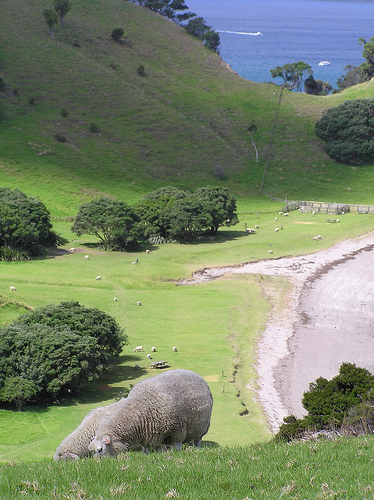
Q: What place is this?
A: It is a field.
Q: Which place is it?
A: It is a field.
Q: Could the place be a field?
A: Yes, it is a field.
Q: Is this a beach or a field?
A: It is a field.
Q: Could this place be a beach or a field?
A: It is a field.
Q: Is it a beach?
A: No, it is a field.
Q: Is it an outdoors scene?
A: Yes, it is outdoors.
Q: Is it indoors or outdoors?
A: It is outdoors.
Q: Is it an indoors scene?
A: No, it is outdoors.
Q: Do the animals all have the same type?
A: Yes, all the animals are sheep.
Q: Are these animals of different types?
A: No, all the animals are sheep.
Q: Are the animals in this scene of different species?
A: No, all the animals are sheep.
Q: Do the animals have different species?
A: No, all the animals are sheep.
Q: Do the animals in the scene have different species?
A: No, all the animals are sheep.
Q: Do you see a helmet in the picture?
A: No, there are no helmets.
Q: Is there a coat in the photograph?
A: Yes, there is a coat.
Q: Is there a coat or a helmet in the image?
A: Yes, there is a coat.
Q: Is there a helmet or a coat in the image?
A: Yes, there is a coat.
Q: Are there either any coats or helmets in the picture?
A: Yes, there is a coat.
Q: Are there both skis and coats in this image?
A: No, there is a coat but no skis.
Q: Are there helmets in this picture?
A: No, there are no helmets.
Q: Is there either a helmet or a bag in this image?
A: No, there are no helmets or bags.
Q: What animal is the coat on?
A: The coat is on the sheep.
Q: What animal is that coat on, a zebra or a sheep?
A: The coat is on a sheep.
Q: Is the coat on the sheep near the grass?
A: Yes, the coat is on the sheep.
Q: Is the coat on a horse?
A: No, the coat is on the sheep.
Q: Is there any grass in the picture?
A: Yes, there is grass.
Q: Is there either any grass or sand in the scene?
A: Yes, there is grass.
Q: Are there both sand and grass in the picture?
A: Yes, there are both grass and sand.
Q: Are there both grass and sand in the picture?
A: Yes, there are both grass and sand.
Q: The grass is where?
A: The grass is on the hill.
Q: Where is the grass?
A: The grass is on the hill.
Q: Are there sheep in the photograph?
A: Yes, there is a sheep.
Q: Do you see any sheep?
A: Yes, there is a sheep.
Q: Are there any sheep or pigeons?
A: Yes, there is a sheep.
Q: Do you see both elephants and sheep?
A: No, there is a sheep but no elephants.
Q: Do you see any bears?
A: No, there are no bears.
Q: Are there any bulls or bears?
A: No, there are no bears or bulls.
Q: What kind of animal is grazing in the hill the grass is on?
A: The animal is a sheep.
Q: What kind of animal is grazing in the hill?
A: The animal is a sheep.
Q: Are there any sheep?
A: Yes, there is a sheep.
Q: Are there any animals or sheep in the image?
A: Yes, there is a sheep.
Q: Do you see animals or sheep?
A: Yes, there is a sheep.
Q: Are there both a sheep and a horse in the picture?
A: No, there is a sheep but no horses.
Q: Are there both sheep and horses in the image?
A: No, there is a sheep but no horses.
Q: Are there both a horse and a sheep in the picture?
A: No, there is a sheep but no horses.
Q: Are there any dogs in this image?
A: No, there are no dogs.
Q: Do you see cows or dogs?
A: No, there are no dogs or cows.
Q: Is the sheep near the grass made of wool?
A: Yes, the sheep is made of wool.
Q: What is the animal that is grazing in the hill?
A: The animal is a sheep.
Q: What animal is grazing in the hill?
A: The animal is a sheep.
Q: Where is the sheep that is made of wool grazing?
A: The sheep is grazing in the hill.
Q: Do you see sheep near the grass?
A: Yes, there is a sheep near the grass.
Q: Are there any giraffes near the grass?
A: No, there is a sheep near the grass.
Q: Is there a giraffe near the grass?
A: No, there is a sheep near the grass.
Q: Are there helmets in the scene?
A: No, there are no helmets.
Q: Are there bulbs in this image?
A: No, there are no bulbs.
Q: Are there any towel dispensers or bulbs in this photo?
A: No, there are no bulbs or towel dispensers.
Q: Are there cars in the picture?
A: No, there are no cars.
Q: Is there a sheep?
A: Yes, there is a sheep.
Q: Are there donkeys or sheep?
A: Yes, there is a sheep.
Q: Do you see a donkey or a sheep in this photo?
A: Yes, there is a sheep.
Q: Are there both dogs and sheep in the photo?
A: No, there is a sheep but no dogs.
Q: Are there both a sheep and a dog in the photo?
A: No, there is a sheep but no dogs.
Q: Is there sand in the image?
A: Yes, there is sand.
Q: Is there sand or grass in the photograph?
A: Yes, there is sand.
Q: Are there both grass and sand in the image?
A: Yes, there are both sand and grass.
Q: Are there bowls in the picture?
A: No, there are no bowls.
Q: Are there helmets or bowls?
A: No, there are no bowls or helmets.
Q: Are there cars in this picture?
A: No, there are no cars.